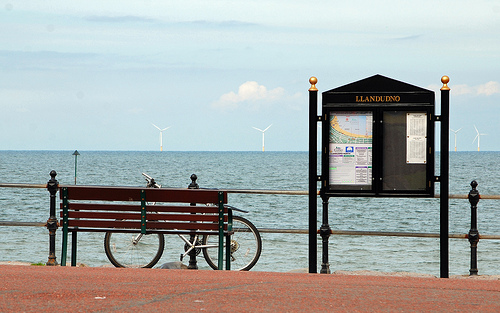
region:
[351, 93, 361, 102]
yellow letter on sign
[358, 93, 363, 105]
yellow letter on sign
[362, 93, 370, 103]
yellow letter on sign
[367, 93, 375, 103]
yellow letter on sign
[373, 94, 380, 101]
yellow letter on sign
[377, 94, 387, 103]
yellow letter on sign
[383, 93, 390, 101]
yellow letter on sign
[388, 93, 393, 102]
yellow letter on sign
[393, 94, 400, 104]
yellow letter on sign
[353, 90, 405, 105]
yellow letters on sign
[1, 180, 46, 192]
piece of iron fence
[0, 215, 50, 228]
piece of iron fence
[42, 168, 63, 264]
piece of iron fence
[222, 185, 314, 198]
piece of iron fence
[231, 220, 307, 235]
piece of iron fence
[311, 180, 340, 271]
piece of iron fence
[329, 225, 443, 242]
piece of iron fence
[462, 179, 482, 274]
piece of iron fence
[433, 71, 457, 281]
piece of iron fence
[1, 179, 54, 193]
piece of iron fence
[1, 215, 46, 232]
piece of iron fence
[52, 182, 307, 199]
piece of iron fence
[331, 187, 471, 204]
piece of iron fence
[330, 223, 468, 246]
piece of iron fence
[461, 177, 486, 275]
piece of iron fence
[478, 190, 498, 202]
piece of iron fence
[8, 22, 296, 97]
The sky is the color blue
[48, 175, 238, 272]
The bench on the ground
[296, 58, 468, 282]
The sign on the ground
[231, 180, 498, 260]
The gate is made of silver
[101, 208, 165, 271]
The front wheel of the tire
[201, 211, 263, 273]
The back wheel of the tire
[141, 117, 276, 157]
The windmill in the ocean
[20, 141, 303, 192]
The ocean water is very calm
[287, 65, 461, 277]
The sign is the color black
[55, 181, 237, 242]
The bench is made of wood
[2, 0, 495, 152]
THE SKY HAS WISPY CLOUDS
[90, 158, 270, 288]
THIS IS A BIKE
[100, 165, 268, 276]
THE BIKE IS PARKED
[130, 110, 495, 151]
THE WINDMILLS ARE IN THE DISTANCE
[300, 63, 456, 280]
THIS SIGN IS BLACK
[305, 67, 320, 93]
THIS IS A GOLD KNOB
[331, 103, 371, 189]
THIS IS A MAP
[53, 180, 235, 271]
THIS IS A BENCH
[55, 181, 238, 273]
THE BENCH IS WOODEN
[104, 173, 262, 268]
large metal silver bike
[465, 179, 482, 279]
short black metal pole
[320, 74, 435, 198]
large black white sign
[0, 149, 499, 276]
large open body of water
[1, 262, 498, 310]
large wide red lot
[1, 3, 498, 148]
large wide open blue sky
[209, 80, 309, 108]
large wide white clouds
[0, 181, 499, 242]
large long metal rail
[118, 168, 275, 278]
A bicycle parked by the bench.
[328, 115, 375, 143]
A map o the board.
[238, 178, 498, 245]
The railing is gray.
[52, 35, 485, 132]
The sky is clear and blue.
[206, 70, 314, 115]
The cloud is white.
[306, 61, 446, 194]
A black poster board.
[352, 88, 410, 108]
The letters are gold.